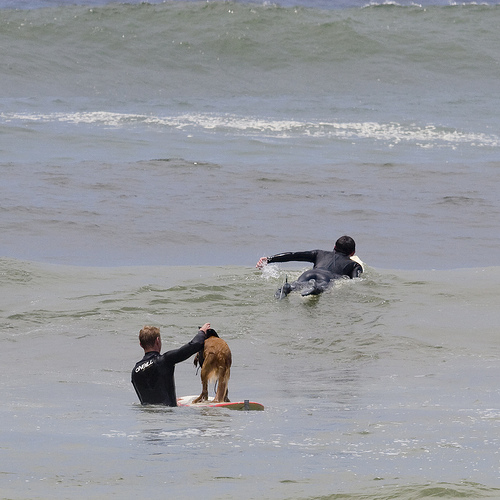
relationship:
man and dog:
[131, 322, 210, 409] [194, 328, 232, 405]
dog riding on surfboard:
[194, 328, 232, 405] [178, 395, 265, 412]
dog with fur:
[194, 328, 232, 405] [195, 337, 231, 404]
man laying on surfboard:
[256, 236, 364, 299] [351, 254, 365, 270]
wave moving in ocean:
[4, 110, 500, 151] [2, 2, 498, 499]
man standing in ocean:
[131, 322, 210, 409] [2, 2, 498, 499]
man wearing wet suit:
[131, 322, 210, 409] [131, 330, 205, 407]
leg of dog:
[194, 360, 213, 405] [194, 328, 232, 405]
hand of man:
[203, 322, 210, 332] [131, 322, 210, 409]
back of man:
[315, 251, 352, 276] [256, 236, 364, 299]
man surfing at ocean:
[256, 236, 364, 299] [2, 2, 498, 499]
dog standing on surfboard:
[194, 328, 232, 405] [178, 395, 265, 412]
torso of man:
[135, 355, 177, 406] [131, 322, 210, 409]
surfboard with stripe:
[178, 395, 265, 412] [210, 401, 264, 409]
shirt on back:
[267, 251, 362, 279] [315, 251, 352, 276]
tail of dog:
[215, 354, 226, 404] [194, 328, 232, 405]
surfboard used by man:
[351, 254, 365, 270] [256, 236, 364, 299]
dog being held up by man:
[194, 328, 232, 405] [131, 322, 210, 409]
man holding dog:
[131, 322, 210, 409] [194, 328, 232, 405]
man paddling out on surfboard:
[256, 236, 364, 299] [351, 254, 365, 270]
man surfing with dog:
[131, 322, 210, 409] [194, 328, 232, 405]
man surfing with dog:
[256, 236, 364, 299] [194, 328, 232, 405]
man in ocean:
[131, 322, 210, 409] [2, 2, 498, 499]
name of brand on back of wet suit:
[135, 357, 156, 372] [131, 330, 205, 407]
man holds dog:
[131, 322, 210, 409] [194, 328, 232, 405]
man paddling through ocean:
[256, 236, 364, 299] [2, 2, 498, 499]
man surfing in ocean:
[256, 236, 364, 299] [2, 2, 498, 499]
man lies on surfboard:
[256, 236, 364, 299] [351, 254, 365, 270]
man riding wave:
[131, 322, 210, 409] [4, 110, 500, 151]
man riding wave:
[256, 236, 364, 299] [4, 110, 500, 151]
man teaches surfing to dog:
[131, 322, 210, 409] [194, 328, 232, 405]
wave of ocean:
[4, 110, 500, 151] [2, 2, 498, 499]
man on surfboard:
[256, 236, 364, 299] [351, 254, 365, 270]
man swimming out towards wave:
[256, 236, 364, 299] [4, 110, 500, 151]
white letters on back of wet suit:
[134, 358, 155, 373] [131, 330, 205, 407]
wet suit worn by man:
[131, 330, 205, 407] [131, 322, 210, 409]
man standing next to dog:
[131, 322, 210, 409] [194, 328, 232, 405]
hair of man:
[333, 236, 355, 255] [256, 236, 364, 299]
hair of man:
[139, 326, 160, 348] [131, 322, 210, 409]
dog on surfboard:
[194, 328, 232, 405] [178, 395, 265, 412]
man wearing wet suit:
[256, 236, 364, 299] [268, 251, 362, 295]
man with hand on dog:
[131, 322, 210, 409] [194, 328, 232, 405]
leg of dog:
[224, 363, 231, 402] [194, 328, 232, 405]